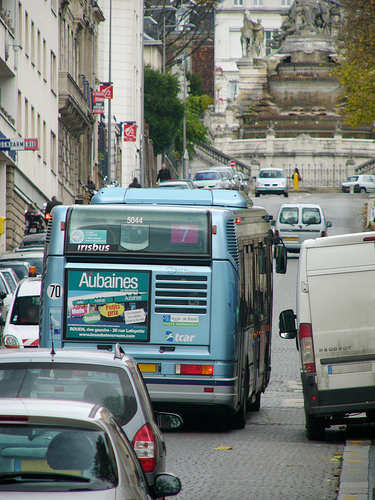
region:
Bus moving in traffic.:
[38, 186, 288, 428]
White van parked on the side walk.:
[278, 229, 373, 440]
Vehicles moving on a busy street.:
[3, 186, 326, 498]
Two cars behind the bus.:
[0, 348, 184, 498]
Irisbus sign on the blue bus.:
[75, 243, 111, 252]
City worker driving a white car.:
[3, 265, 40, 347]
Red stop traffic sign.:
[226, 154, 238, 166]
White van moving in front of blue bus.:
[271, 201, 331, 256]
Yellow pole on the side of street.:
[291, 171, 299, 191]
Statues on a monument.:
[235, 1, 340, 62]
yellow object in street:
[203, 440, 255, 473]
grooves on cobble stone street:
[214, 459, 275, 479]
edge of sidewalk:
[326, 464, 348, 486]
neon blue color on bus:
[110, 178, 243, 207]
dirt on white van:
[317, 334, 365, 380]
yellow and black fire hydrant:
[290, 159, 308, 203]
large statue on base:
[241, 10, 268, 66]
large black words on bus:
[33, 279, 79, 318]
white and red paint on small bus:
[15, 330, 40, 346]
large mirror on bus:
[262, 230, 298, 292]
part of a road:
[264, 446, 312, 473]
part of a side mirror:
[167, 414, 183, 442]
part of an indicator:
[191, 363, 209, 375]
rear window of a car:
[46, 372, 113, 397]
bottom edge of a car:
[322, 403, 364, 421]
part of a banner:
[97, 288, 143, 335]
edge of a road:
[327, 445, 353, 490]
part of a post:
[134, 87, 143, 165]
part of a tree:
[133, 45, 178, 123]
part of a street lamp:
[179, 16, 196, 33]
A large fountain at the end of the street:
[224, 0, 371, 148]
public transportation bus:
[38, 187, 283, 407]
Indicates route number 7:
[166, 202, 204, 251]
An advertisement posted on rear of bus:
[65, 259, 157, 343]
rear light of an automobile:
[113, 411, 163, 477]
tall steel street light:
[155, 10, 197, 148]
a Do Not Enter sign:
[219, 154, 243, 173]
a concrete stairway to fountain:
[191, 116, 259, 179]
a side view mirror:
[265, 295, 301, 352]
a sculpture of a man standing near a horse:
[232, 5, 274, 59]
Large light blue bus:
[44, 191, 289, 403]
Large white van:
[278, 237, 373, 445]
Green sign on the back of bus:
[62, 266, 149, 339]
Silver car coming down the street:
[252, 159, 291, 200]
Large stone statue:
[195, 2, 369, 176]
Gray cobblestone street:
[184, 436, 336, 499]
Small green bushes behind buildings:
[143, 61, 212, 164]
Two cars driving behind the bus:
[1, 345, 168, 498]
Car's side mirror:
[153, 408, 186, 432]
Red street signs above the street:
[89, 87, 147, 147]